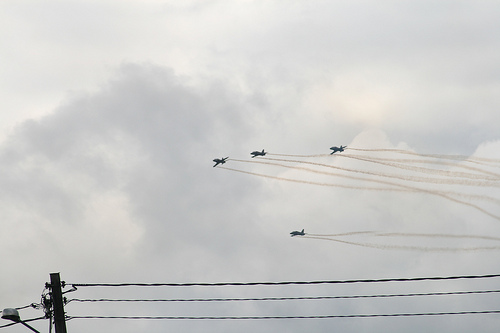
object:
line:
[60, 274, 499, 287]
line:
[60, 290, 500, 304]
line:
[60, 310, 500, 319]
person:
[286, 119, 428, 203]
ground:
[404, 166, 459, 215]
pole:
[46, 272, 68, 333]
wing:
[213, 162, 220, 168]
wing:
[251, 154, 256, 158]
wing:
[330, 150, 336, 155]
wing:
[291, 234, 296, 237]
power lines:
[64, 273, 499, 321]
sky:
[1, 1, 498, 331]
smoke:
[219, 147, 500, 252]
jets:
[213, 144, 350, 238]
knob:
[44, 281, 53, 292]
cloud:
[4, 16, 497, 331]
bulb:
[2, 308, 20, 319]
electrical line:
[7, 267, 499, 332]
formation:
[204, 129, 364, 239]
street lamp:
[1, 307, 21, 322]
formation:
[203, 163, 335, 247]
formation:
[345, 170, 438, 239]